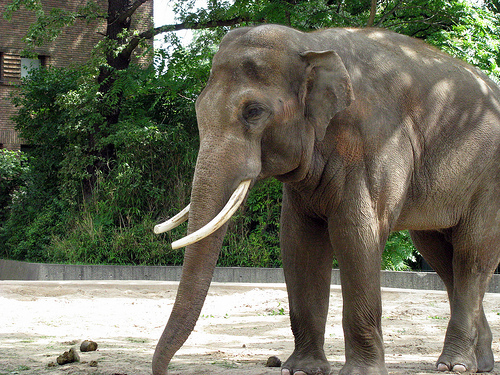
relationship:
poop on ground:
[46, 333, 125, 373] [89, 353, 129, 373]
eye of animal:
[237, 98, 265, 122] [135, 13, 500, 375]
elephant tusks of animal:
[167, 176, 252, 252] [135, 13, 496, 355]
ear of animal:
[305, 57, 352, 139] [135, 13, 500, 375]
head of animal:
[193, 24, 356, 189] [135, 13, 500, 375]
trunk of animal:
[151, 133, 258, 371] [135, 13, 500, 375]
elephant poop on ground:
[76, 336, 102, 352] [1, 284, 498, 374]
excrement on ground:
[256, 340, 277, 369] [214, 330, 242, 371]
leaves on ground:
[263, 300, 288, 322] [9, 271, 498, 368]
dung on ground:
[56, 352, 76, 367] [49, 302, 146, 335]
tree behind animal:
[7, 0, 261, 196] [135, 13, 500, 375]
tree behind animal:
[0, 0, 499, 270] [135, 13, 500, 375]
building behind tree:
[2, 3, 160, 178] [47, 9, 158, 229]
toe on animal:
[437, 361, 449, 371] [135, 13, 500, 375]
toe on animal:
[451, 362, 464, 369] [135, 13, 500, 375]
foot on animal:
[430, 340, 480, 372] [135, 13, 500, 375]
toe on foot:
[437, 361, 449, 371] [430, 340, 480, 372]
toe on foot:
[451, 362, 464, 369] [430, 340, 480, 372]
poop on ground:
[46, 333, 110, 372] [9, 271, 498, 368]